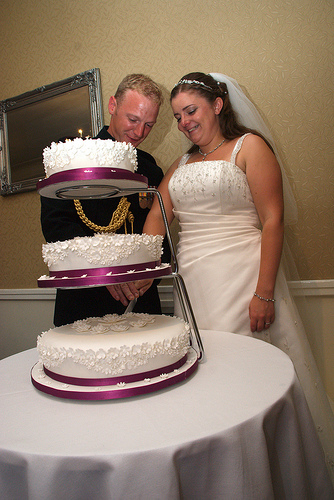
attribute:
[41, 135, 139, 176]
frosting — white 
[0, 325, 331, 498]
linen — white 